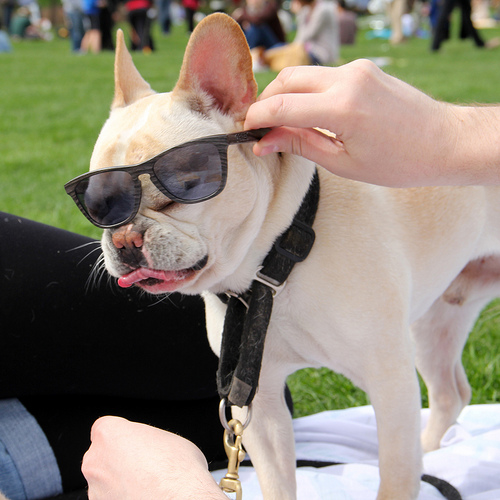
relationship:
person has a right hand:
[80, 58, 499, 500] [242, 58, 499, 189]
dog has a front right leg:
[65, 11, 499, 499] [200, 289, 313, 499]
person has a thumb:
[80, 58, 499, 500] [252, 125, 351, 179]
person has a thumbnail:
[80, 58, 499, 500] [259, 142, 281, 156]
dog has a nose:
[65, 11, 499, 499] [111, 223, 149, 266]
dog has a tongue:
[65, 11, 499, 499] [117, 267, 186, 288]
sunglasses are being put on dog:
[64, 127, 272, 229] [65, 11, 499, 499]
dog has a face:
[65, 11, 499, 499] [84, 153, 224, 296]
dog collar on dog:
[215, 164, 320, 409] [65, 11, 499, 499]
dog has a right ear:
[65, 11, 499, 499] [110, 28, 158, 111]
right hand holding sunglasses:
[242, 58, 499, 189] [64, 127, 272, 229]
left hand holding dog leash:
[81, 415, 233, 500] [215, 165, 320, 499]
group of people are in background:
[0, 0, 500, 68] [0, 0, 499, 240]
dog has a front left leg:
[65, 11, 499, 499] [307, 226, 424, 499]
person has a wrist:
[80, 58, 499, 500] [442, 101, 500, 186]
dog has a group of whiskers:
[65, 11, 499, 499] [65, 240, 122, 296]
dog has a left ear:
[65, 11, 499, 499] [171, 11, 259, 129]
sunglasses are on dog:
[64, 127, 272, 229] [65, 11, 499, 499]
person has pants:
[95, 0, 114, 51] [97, 8, 115, 51]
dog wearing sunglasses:
[65, 11, 499, 499] [64, 127, 272, 229]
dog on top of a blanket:
[65, 11, 499, 499] [210, 403, 500, 499]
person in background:
[271, 0, 343, 66] [0, 0, 499, 240]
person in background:
[232, 0, 287, 49] [0, 0, 499, 240]